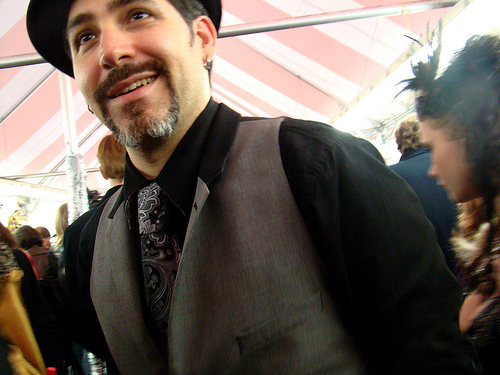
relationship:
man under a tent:
[26, 0, 461, 369] [4, 0, 437, 196]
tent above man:
[4, 0, 437, 196] [26, 0, 461, 369]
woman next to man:
[403, 55, 499, 349] [26, 0, 461, 369]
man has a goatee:
[26, 0, 461, 369] [94, 64, 181, 146]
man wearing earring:
[26, 0, 461, 369] [203, 57, 218, 73]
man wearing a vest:
[26, 0, 461, 369] [78, 116, 356, 373]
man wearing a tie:
[26, 0, 461, 369] [126, 182, 186, 334]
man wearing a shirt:
[26, 0, 461, 369] [73, 125, 463, 373]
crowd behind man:
[0, 185, 104, 364] [26, 0, 461, 369]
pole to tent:
[3, 0, 444, 72] [4, 0, 437, 196]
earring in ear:
[203, 57, 218, 73] [193, 14, 217, 72]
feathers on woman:
[394, 24, 448, 97] [403, 55, 499, 349]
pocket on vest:
[232, 292, 345, 351] [78, 116, 356, 373]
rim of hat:
[24, 4, 39, 39] [28, 0, 234, 72]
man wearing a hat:
[26, 0, 461, 369] [28, 0, 234, 72]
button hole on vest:
[192, 198, 205, 213] [78, 116, 356, 373]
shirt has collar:
[73, 125, 463, 373] [112, 99, 225, 215]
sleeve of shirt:
[292, 137, 479, 369] [73, 125, 463, 373]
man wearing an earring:
[26, 0, 461, 369] [203, 57, 218, 73]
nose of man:
[96, 26, 142, 68] [26, 0, 461, 369]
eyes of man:
[69, 5, 159, 47] [26, 0, 461, 369]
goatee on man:
[94, 64, 181, 146] [26, 0, 461, 369]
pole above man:
[3, 0, 444, 72] [26, 0, 461, 369]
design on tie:
[137, 240, 169, 286] [126, 182, 186, 334]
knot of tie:
[139, 188, 171, 231] [126, 182, 186, 334]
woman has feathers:
[403, 55, 499, 349] [394, 24, 448, 97]